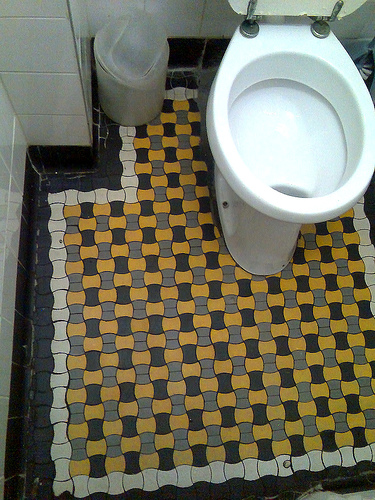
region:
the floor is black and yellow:
[140, 340, 209, 407]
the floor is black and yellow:
[162, 311, 248, 435]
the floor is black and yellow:
[176, 349, 252, 469]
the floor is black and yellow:
[181, 393, 245, 481]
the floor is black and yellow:
[144, 394, 206, 495]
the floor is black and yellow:
[128, 394, 182, 497]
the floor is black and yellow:
[159, 351, 217, 443]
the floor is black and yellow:
[171, 410, 222, 495]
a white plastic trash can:
[97, 18, 172, 119]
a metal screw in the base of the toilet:
[218, 189, 231, 213]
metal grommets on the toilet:
[243, 20, 336, 35]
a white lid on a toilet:
[266, 2, 326, 15]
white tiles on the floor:
[123, 471, 231, 485]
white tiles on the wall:
[2, 190, 20, 236]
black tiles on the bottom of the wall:
[11, 343, 21, 460]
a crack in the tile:
[284, 454, 293, 469]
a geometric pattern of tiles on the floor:
[108, 261, 223, 356]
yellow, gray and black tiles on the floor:
[265, 399, 338, 438]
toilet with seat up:
[204, 16, 370, 261]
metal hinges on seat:
[233, 5, 348, 44]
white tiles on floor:
[6, 53, 60, 142]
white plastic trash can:
[92, 13, 172, 130]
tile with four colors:
[47, 267, 118, 298]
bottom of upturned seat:
[232, 1, 361, 21]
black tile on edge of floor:
[30, 266, 53, 377]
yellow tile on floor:
[60, 202, 82, 220]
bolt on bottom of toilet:
[216, 194, 232, 213]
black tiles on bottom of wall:
[8, 260, 30, 348]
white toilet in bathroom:
[178, 26, 362, 279]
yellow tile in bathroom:
[101, 420, 118, 435]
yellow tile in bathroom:
[135, 420, 155, 433]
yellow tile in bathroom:
[167, 417, 188, 432]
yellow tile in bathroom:
[198, 409, 221, 425]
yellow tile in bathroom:
[232, 408, 256, 424]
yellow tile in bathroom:
[267, 406, 284, 419]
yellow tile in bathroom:
[298, 403, 316, 418]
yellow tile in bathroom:
[325, 394, 348, 414]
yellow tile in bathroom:
[207, 444, 226, 461]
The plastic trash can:
[86, 9, 169, 123]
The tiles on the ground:
[20, 62, 373, 499]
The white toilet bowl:
[200, 0, 374, 280]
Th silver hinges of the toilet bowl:
[236, 0, 344, 42]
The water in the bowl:
[229, 91, 330, 198]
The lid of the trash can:
[90, 10, 174, 91]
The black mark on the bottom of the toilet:
[218, 196, 233, 210]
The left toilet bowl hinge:
[238, 0, 266, 41]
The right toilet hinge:
[308, 0, 346, 42]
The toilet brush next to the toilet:
[343, 22, 374, 86]